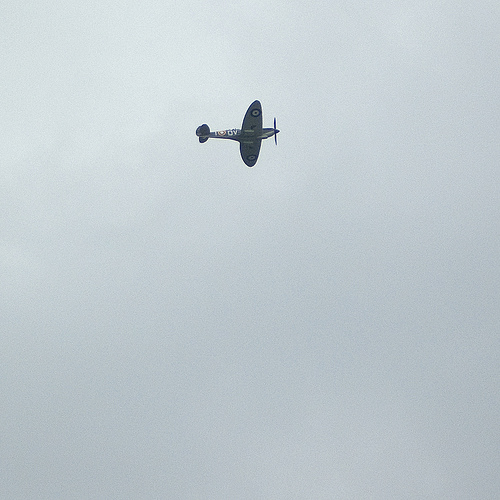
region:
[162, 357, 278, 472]
the sky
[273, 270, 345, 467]
the sky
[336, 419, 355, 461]
the sky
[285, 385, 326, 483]
the sky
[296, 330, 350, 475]
the sky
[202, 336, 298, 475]
the sky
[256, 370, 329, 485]
the sky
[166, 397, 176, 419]
the sky is cloudy and dark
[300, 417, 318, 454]
the sky is cloudy and dark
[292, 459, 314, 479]
the sky is cloudy and dark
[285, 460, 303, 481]
the sky is cloudy and dark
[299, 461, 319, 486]
the sky is cloudy and dark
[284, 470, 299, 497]
the sky is cloudy and dark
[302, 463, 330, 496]
the sky is cloudy and dark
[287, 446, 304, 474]
the sky is cloudy and dark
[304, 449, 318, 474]
the sky is cloudy and dark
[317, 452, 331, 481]
the sky is cloudy and dark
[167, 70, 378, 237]
an airplane is flying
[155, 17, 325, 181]
an airplane is flying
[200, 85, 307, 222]
an airplane is flying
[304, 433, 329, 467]
the sky is clear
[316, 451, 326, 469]
the sky is clear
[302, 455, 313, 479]
the sky is clear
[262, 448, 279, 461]
the sky is clear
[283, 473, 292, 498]
the sky is clear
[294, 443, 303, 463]
the sky is clear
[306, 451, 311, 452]
the sky is clear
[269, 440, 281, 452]
the sky is clear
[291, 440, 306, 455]
the sky is clear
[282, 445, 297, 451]
the sky is clear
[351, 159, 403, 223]
part of the sky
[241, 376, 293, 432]
part of a cloud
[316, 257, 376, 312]
part of a clear sky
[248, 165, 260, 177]
edge of a wing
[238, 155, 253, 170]
edge of a wing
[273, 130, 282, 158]
part of a propellor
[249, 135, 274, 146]
part of a plane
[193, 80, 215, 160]
part of a tail wing